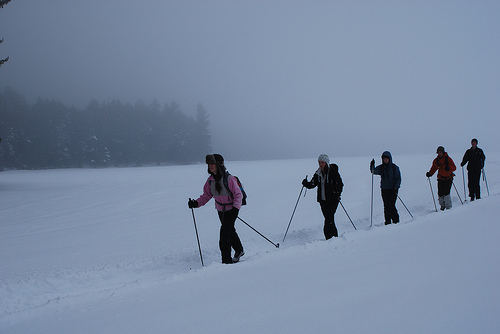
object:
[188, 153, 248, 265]
skier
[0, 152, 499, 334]
snow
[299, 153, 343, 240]
skier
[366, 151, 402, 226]
skier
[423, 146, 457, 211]
skier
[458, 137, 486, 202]
skier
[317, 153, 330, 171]
head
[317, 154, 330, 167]
hat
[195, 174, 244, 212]
jacket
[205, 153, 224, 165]
hat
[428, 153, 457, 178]
jacket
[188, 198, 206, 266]
pole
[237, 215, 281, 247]
pole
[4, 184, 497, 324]
ditch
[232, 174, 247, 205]
backpack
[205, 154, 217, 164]
fur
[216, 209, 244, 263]
pants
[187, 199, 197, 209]
hand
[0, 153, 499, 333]
ground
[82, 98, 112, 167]
tree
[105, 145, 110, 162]
branches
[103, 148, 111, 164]
snow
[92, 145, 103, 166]
branches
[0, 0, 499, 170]
fog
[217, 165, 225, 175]
ear flap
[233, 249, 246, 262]
boot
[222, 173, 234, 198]
shoulder strap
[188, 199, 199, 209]
glove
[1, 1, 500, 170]
distance